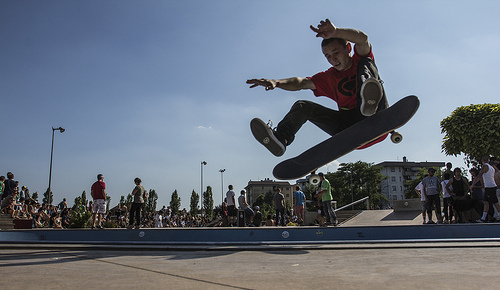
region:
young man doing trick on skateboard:
[234, 9, 422, 188]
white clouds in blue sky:
[25, 22, 66, 72]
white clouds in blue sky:
[129, 46, 165, 101]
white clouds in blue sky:
[160, 48, 195, 96]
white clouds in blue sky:
[94, 95, 147, 144]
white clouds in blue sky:
[385, 16, 422, 49]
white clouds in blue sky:
[422, 41, 457, 65]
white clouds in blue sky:
[126, 4, 167, 98]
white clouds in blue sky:
[173, 28, 213, 102]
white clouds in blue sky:
[120, 98, 184, 151]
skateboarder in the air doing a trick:
[230, 17, 431, 186]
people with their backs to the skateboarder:
[79, 163, 167, 236]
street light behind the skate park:
[39, 112, 71, 222]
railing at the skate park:
[336, 189, 369, 228]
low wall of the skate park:
[179, 225, 266, 257]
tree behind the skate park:
[440, 85, 496, 182]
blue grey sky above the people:
[62, 33, 185, 114]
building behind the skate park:
[348, 156, 441, 221]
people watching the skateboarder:
[419, 156, 474, 217]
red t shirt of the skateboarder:
[303, 65, 374, 105]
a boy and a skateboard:
[244, 18, 420, 197]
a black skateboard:
[269, 97, 428, 185]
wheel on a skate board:
[384, 131, 409, 146]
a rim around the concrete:
[101, 225, 431, 246]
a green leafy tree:
[436, 103, 499, 163]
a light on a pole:
[47, 117, 65, 221]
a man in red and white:
[86, 173, 110, 228]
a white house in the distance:
[373, 160, 425, 206]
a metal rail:
[330, 192, 374, 217]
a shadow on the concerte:
[14, 240, 286, 267]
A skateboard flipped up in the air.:
[270, 94, 421, 184]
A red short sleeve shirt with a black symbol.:
[308, 49, 374, 112]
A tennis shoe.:
[247, 117, 289, 159]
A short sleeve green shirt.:
[317, 180, 334, 205]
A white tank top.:
[480, 164, 495, 190]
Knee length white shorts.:
[91, 197, 106, 214]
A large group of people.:
[0, 171, 343, 228]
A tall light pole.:
[45, 127, 65, 207]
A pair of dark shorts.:
[484, 186, 497, 207]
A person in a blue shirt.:
[290, 184, 307, 224]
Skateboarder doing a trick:
[246, 19, 421, 182]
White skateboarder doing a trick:
[246, 16, 422, 186]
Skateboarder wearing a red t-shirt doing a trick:
[245, 16, 421, 188]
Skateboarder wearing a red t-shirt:
[243, 17, 423, 190]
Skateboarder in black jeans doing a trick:
[243, 15, 423, 188]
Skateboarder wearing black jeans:
[244, 16, 422, 186]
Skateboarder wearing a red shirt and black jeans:
[246, 16, 422, 186]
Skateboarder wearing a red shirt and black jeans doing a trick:
[244, 17, 421, 187]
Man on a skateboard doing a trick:
[245, 17, 420, 184]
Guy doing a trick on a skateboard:
[246, 18, 422, 187]